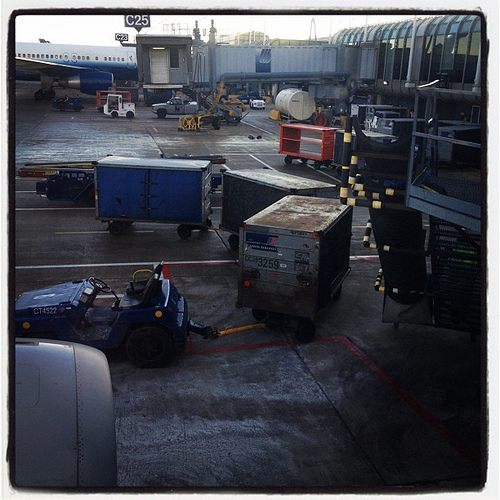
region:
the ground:
[258, 448, 288, 483]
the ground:
[280, 477, 310, 497]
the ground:
[264, 410, 308, 485]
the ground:
[295, 411, 343, 496]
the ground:
[230, 414, 328, 498]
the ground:
[242, 344, 346, 432]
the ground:
[273, 346, 349, 491]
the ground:
[266, 393, 333, 473]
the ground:
[204, 397, 268, 494]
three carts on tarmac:
[89, 150, 360, 335]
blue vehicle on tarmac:
[22, 260, 218, 377]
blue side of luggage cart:
[104, 168, 195, 224]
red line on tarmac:
[332, 325, 411, 404]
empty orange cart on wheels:
[273, 120, 337, 165]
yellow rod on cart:
[215, 307, 283, 345]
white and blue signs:
[112, 15, 150, 45]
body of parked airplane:
[60, 41, 126, 81]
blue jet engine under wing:
[73, 66, 121, 101]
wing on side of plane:
[16, 53, 92, 85]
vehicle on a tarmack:
[31, 250, 193, 351]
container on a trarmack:
[243, 192, 343, 288]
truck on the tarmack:
[40, 163, 89, 221]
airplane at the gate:
[18, 31, 139, 100]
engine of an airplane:
[18, 344, 139, 491]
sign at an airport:
[120, 13, 168, 45]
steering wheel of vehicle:
[84, 270, 114, 310]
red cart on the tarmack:
[276, 115, 345, 180]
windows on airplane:
[95, 52, 150, 66]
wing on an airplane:
[15, 37, 96, 86]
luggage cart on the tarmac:
[234, 190, 359, 342]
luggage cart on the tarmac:
[88, 154, 223, 238]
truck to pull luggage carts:
[10, 255, 217, 371]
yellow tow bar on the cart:
[209, 316, 274, 343]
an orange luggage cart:
[264, 118, 335, 166]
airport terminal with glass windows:
[326, 6, 486, 98]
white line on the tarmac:
[22, 252, 239, 279]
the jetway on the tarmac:
[123, 33, 338, 100]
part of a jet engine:
[9, 328, 133, 490]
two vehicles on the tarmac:
[96, 88, 205, 130]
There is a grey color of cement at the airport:
[298, 375, 351, 465]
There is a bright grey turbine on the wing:
[49, 340, 130, 477]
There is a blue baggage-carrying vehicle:
[16, 276, 196, 371]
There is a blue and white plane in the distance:
[16, 37, 140, 113]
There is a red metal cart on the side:
[281, 111, 343, 176]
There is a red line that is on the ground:
[348, 367, 436, 437]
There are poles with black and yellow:
[333, 142, 361, 186]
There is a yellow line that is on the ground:
[68, 222, 81, 257]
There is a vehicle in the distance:
[50, 160, 105, 222]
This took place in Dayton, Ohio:
[96, 155, 374, 485]